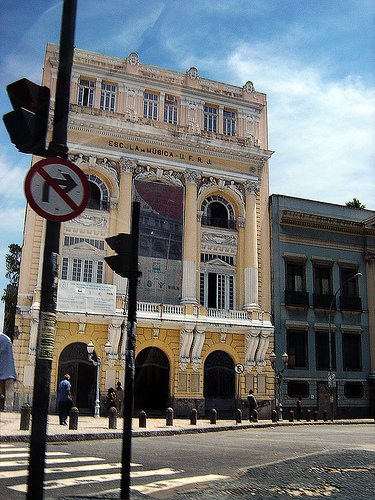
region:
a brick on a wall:
[11, 337, 24, 345]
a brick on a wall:
[12, 351, 28, 359]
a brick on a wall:
[17, 346, 32, 354]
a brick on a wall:
[56, 321, 72, 329]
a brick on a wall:
[55, 333, 64, 341]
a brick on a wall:
[165, 326, 179, 337]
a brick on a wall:
[176, 365, 189, 375]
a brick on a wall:
[240, 367, 255, 375]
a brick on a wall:
[242, 376, 247, 382]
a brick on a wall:
[205, 335, 211, 343]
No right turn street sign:
[21, 155, 92, 226]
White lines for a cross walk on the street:
[4, 423, 219, 493]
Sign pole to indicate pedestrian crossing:
[104, 200, 142, 486]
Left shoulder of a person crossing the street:
[1, 313, 20, 446]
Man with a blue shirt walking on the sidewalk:
[59, 374, 76, 430]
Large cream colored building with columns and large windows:
[30, 137, 275, 336]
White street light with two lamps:
[85, 339, 115, 426]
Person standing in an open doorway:
[79, 367, 98, 412]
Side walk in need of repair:
[253, 456, 374, 496]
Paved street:
[185, 433, 326, 460]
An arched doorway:
[129, 335, 170, 416]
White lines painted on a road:
[10, 457, 177, 493]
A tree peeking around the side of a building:
[1, 240, 23, 324]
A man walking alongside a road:
[51, 365, 84, 427]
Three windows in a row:
[279, 245, 369, 319]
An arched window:
[191, 169, 254, 233]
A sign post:
[119, 199, 145, 410]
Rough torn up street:
[273, 450, 366, 495]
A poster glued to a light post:
[33, 306, 65, 366]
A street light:
[324, 262, 368, 422]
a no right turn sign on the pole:
[23, 158, 87, 222]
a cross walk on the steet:
[0, 443, 230, 498]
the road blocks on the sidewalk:
[9, 397, 332, 427]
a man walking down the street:
[53, 372, 74, 425]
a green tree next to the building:
[3, 240, 20, 342]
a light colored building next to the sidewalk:
[31, 61, 277, 423]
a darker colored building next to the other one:
[270, 193, 370, 413]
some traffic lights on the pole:
[100, 230, 130, 281]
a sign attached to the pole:
[54, 279, 121, 316]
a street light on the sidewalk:
[85, 342, 115, 419]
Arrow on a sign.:
[20, 151, 93, 228]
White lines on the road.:
[5, 438, 149, 494]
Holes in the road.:
[248, 459, 373, 498]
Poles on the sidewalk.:
[51, 398, 336, 425]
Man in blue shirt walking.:
[51, 369, 78, 425]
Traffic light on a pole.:
[4, 66, 60, 156]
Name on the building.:
[101, 126, 230, 170]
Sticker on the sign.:
[36, 304, 63, 363]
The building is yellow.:
[34, 285, 276, 378]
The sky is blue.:
[257, 12, 353, 73]